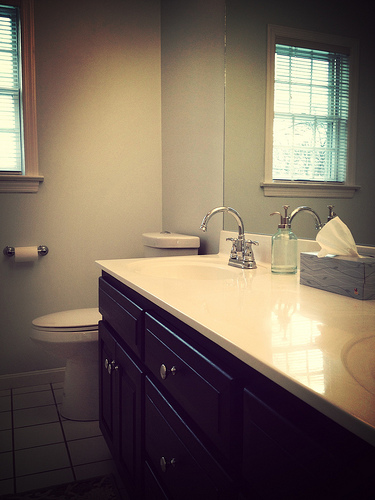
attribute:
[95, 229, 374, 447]
vanity — dark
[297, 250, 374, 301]
box — grey, wavy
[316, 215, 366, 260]
tissue — white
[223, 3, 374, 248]
mirror — large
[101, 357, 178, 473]
hardware — silver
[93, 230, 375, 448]
countertop — long, white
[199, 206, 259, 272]
faucet — silver, stainless steel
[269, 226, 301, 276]
glass — greenish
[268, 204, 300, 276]
bottle — pump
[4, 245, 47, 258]
holder — silver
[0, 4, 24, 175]
mini blinds — open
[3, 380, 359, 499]
tile — black, white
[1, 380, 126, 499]
floor — tile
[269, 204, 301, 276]
soap dispenser — clear, silver, nearly empty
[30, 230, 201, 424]
toilet — white, porcelain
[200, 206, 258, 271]
sink faucet — chrome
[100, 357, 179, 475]
drawer pulls — silver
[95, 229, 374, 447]
counter top — white